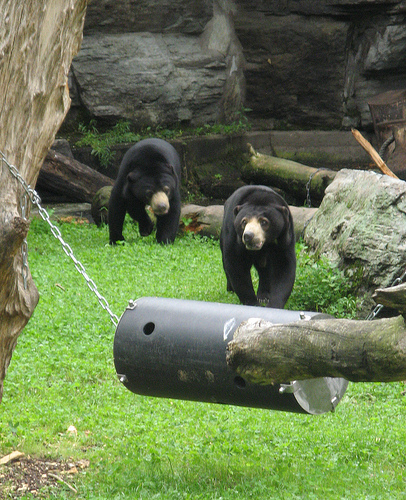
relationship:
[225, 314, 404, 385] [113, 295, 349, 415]
tree branch next to barrel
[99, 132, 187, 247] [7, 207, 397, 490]
bear on grass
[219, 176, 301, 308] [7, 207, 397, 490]
bear on grass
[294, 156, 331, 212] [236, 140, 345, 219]
chain on log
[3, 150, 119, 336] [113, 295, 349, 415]
chain on barrel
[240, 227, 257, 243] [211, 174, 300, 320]
nose on bear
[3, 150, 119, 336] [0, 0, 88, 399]
chain tied to tree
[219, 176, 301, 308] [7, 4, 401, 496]
bear walking around at zoo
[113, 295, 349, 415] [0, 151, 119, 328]
barrel attached with chain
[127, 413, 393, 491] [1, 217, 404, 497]
grass on ground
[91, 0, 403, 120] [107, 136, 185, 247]
wall behind bear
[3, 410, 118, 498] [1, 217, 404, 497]
dirt on ground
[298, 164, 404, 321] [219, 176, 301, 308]
rock next to bear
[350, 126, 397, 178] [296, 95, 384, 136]
branch growing out of wall